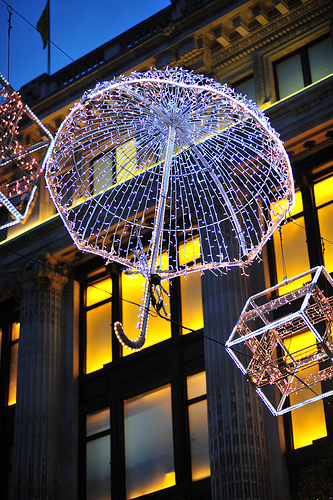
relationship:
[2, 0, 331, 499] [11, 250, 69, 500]
building has a pillar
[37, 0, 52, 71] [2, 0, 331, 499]
flag on top of building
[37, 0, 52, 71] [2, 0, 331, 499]
flag on building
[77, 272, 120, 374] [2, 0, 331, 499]
window on building